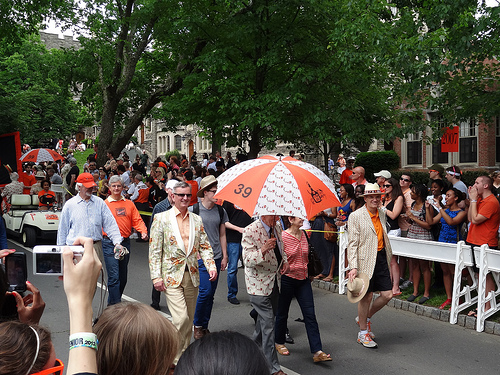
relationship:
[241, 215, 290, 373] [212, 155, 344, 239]
man holding umbrella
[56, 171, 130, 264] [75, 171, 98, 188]
man wearing cap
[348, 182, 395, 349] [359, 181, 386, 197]
man has hat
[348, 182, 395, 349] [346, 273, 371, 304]
man has hat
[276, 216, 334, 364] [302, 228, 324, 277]
woman carrying purse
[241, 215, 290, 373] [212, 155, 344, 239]
man carrying umbrella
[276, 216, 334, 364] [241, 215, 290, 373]
woman next to man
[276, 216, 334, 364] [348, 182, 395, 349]
woman next to man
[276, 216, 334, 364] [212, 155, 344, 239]
woman under umbrella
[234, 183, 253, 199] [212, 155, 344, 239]
number 39 on umbrella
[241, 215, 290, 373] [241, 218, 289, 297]
man wearing blazer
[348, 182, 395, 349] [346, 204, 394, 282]
man wearing blazer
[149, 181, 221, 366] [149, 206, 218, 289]
man wearing blazer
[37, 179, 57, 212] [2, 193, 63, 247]
woman driving golf cart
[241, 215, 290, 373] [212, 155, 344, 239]
man under umbrella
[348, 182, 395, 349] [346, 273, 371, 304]
man holding hat